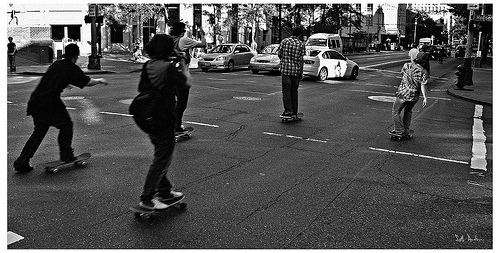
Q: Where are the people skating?
A: On the street.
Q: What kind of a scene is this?
A: City.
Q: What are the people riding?
A: Skateboards.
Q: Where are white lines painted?
A: On the road.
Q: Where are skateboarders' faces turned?
A: Away from the camera.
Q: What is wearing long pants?
A: The skateboarders.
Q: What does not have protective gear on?
A: The skateboard riders.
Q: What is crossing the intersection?
A: The skateboarders.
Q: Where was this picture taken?
A: On a city street.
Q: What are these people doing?
A: Skateboarding.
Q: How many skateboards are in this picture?
A: 5.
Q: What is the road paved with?
A: Asphalt.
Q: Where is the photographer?
A: Behind the skateboarders.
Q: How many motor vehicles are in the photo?
A: Four.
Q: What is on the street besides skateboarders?
A: Motor vehicles.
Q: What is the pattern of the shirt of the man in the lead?
A: Plaid.